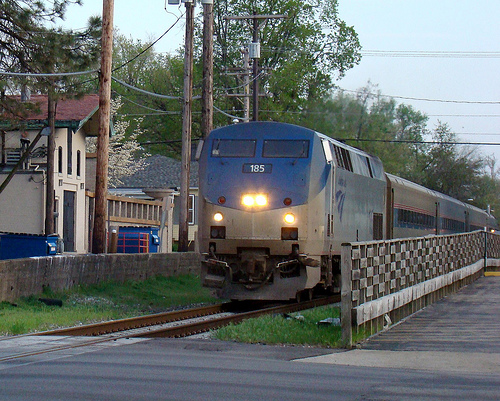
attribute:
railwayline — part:
[46, 313, 349, 341]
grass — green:
[17, 302, 343, 350]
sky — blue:
[131, 4, 496, 89]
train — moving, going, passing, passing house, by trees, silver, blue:
[208, 121, 418, 190]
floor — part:
[6, 337, 127, 356]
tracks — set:
[87, 310, 290, 348]